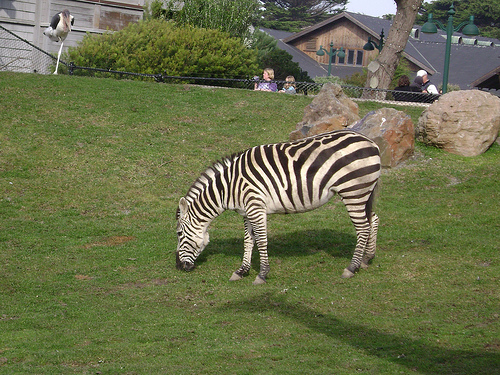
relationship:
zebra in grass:
[175, 127, 382, 286] [0, 68, 498, 374]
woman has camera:
[250, 67, 279, 95] [250, 73, 259, 84]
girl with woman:
[280, 73, 298, 96] [250, 67, 279, 95]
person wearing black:
[392, 75, 411, 103] [393, 85, 409, 101]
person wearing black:
[412, 76, 429, 103] [411, 85, 425, 103]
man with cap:
[414, 67, 441, 97] [416, 67, 428, 78]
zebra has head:
[175, 127, 382, 286] [173, 195, 214, 273]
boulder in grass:
[286, 78, 360, 144] [0, 68, 498, 374]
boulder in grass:
[348, 105, 417, 171] [0, 68, 498, 374]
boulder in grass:
[412, 86, 499, 158] [0, 68, 498, 374]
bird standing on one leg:
[41, 6, 77, 76] [50, 38, 66, 76]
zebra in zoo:
[175, 127, 382, 286] [1, 0, 499, 373]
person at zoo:
[392, 75, 411, 103] [1, 0, 499, 373]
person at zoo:
[412, 76, 429, 103] [1, 0, 499, 373]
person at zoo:
[416, 68, 438, 95] [1, 0, 499, 373]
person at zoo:
[250, 67, 279, 95] [1, 0, 499, 373]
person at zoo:
[280, 73, 298, 96] [1, 0, 499, 373]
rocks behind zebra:
[284, 80, 500, 169] [175, 127, 382, 286]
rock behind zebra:
[286, 78, 360, 144] [175, 127, 382, 286]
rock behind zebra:
[348, 105, 417, 171] [175, 127, 382, 286]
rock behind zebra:
[412, 86, 499, 158] [175, 127, 382, 286]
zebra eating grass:
[175, 127, 382, 286] [0, 68, 498, 374]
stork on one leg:
[41, 6, 77, 76] [50, 38, 66, 76]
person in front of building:
[392, 75, 411, 103] [255, 9, 499, 107]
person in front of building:
[412, 76, 429, 103] [255, 9, 499, 107]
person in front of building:
[416, 68, 438, 95] [255, 9, 499, 107]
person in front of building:
[280, 73, 298, 96] [255, 9, 499, 107]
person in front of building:
[250, 67, 279, 95] [255, 9, 499, 107]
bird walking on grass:
[41, 6, 77, 76] [0, 68, 498, 374]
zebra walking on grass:
[175, 127, 382, 286] [0, 68, 498, 374]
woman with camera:
[250, 67, 279, 95] [250, 73, 259, 84]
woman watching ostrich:
[250, 67, 279, 95] [41, 6, 77, 76]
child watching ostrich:
[280, 73, 298, 96] [41, 6, 77, 76]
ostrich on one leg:
[41, 6, 77, 76] [50, 38, 66, 76]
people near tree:
[392, 67, 441, 106] [360, 1, 426, 100]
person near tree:
[392, 75, 411, 103] [360, 1, 426, 100]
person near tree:
[412, 76, 429, 103] [360, 1, 426, 100]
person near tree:
[416, 68, 438, 95] [360, 1, 426, 100]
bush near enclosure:
[53, 18, 254, 90] [1, 25, 443, 106]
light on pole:
[419, 11, 439, 38] [441, 2, 456, 96]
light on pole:
[460, 13, 480, 38] [441, 2, 456, 96]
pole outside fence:
[441, 2, 456, 96] [1, 25, 443, 106]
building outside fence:
[3, 0, 185, 76] [1, 25, 443, 106]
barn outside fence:
[3, 0, 185, 76] [1, 25, 443, 106]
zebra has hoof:
[175, 127, 382, 286] [253, 274, 265, 285]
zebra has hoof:
[175, 127, 382, 286] [227, 270, 243, 280]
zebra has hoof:
[175, 127, 382, 286] [339, 265, 354, 279]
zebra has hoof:
[175, 127, 382, 286] [359, 260, 370, 271]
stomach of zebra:
[266, 168, 334, 220] [175, 127, 382, 286]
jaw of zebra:
[181, 219, 208, 248] [175, 127, 382, 286]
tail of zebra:
[363, 183, 375, 228] [175, 127, 382, 286]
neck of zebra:
[188, 156, 236, 226] [175, 127, 382, 286]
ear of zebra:
[177, 194, 189, 219] [175, 127, 382, 286]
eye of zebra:
[176, 228, 182, 237] [175, 127, 382, 286]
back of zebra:
[252, 127, 351, 159] [175, 127, 382, 286]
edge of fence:
[0, 15, 14, 72] [1, 25, 443, 106]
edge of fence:
[427, 88, 439, 106] [1, 25, 443, 106]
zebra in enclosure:
[175, 127, 382, 286] [1, 26, 500, 373]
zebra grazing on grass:
[175, 127, 382, 286] [0, 68, 498, 374]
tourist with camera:
[250, 67, 279, 95] [250, 73, 259, 84]